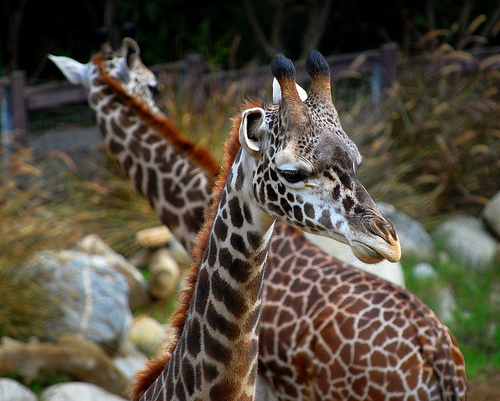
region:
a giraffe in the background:
[70, 41, 473, 378]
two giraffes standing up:
[67, 52, 486, 385]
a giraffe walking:
[152, 68, 408, 378]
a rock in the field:
[16, 251, 117, 324]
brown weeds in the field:
[12, 167, 81, 339]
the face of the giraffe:
[228, 58, 413, 260]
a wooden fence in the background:
[10, 58, 434, 133]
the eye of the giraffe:
[279, 161, 317, 183]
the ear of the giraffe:
[236, 105, 279, 152]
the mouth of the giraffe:
[323, 193, 391, 248]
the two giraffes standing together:
[38, 26, 468, 398]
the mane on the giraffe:
[90, 50, 220, 175]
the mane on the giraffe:
[127, 95, 262, 397]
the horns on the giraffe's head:
[270, 48, 331, 108]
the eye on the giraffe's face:
[273, 166, 310, 182]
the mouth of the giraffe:
[350, 234, 402, 264]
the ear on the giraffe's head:
[236, 107, 266, 160]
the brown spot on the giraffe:
[227, 195, 242, 227]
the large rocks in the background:
[1, 189, 498, 399]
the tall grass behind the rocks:
[0, 15, 495, 340]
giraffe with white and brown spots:
[208, 269, 246, 367]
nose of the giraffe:
[367, 215, 399, 244]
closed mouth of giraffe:
[353, 239, 383, 261]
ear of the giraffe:
[48, 40, 143, 82]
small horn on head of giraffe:
[268, 49, 331, 111]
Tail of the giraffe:
[421, 329, 455, 399]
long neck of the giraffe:
[176, 215, 276, 395]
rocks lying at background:
[17, 249, 131, 346]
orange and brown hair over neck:
[169, 132, 217, 172]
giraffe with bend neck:
[48, 40, 183, 161]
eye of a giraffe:
[267, 150, 314, 190]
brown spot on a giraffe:
[209, 267, 251, 324]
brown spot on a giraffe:
[330, 309, 360, 341]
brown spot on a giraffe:
[317, 316, 344, 356]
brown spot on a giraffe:
[366, 288, 392, 307]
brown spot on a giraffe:
[273, 306, 293, 326]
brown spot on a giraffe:
[244, 226, 268, 251]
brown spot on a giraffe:
[240, 196, 257, 228]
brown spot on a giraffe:
[298, 198, 319, 220]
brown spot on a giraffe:
[263, 179, 281, 204]